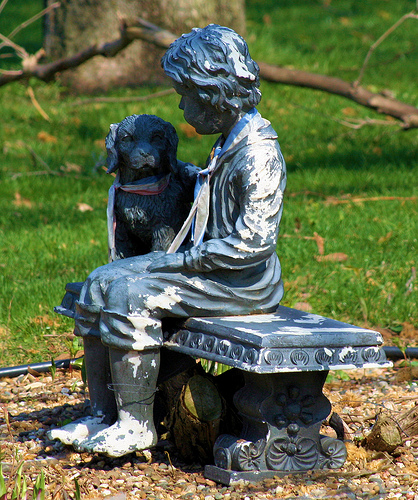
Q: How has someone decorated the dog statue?
A: With scarf.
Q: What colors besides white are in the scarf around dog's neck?
A: Blue and red.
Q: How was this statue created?
A: From metal.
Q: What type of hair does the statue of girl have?
A: Short.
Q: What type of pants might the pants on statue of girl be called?
A: Pantaloons.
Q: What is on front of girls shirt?
A: Long ribbon.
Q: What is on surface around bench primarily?
A: Rocks.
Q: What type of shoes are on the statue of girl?
A: Boots.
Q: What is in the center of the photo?
A: A statue.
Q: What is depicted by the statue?
A: A dog and child on a bench.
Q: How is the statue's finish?
A: Peeling.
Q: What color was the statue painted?
A: Grey.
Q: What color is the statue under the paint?
A: White.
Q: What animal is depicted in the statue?
A: A dog.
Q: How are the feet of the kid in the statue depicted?
A: Bare feet.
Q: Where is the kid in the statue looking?
A: At the dog.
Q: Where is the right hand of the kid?
A: On the dog's back.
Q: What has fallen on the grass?
A: A branch.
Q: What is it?
A: Statue.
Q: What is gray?
A: Dog.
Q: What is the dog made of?
A: Stone.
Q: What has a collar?
A: Dog.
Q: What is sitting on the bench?
A: Boy.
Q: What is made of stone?
A: Boy.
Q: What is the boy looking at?
A: The dog.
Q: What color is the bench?
A: Gray.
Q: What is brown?
A: The tree branch.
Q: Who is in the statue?
A: A girl.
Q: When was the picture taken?
A: Daytime.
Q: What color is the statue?
A: Silver.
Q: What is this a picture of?
A: Statue.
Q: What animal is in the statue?
A: A dog.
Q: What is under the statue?
A: Stones.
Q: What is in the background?
A: A branch.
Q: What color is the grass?
A: Green.